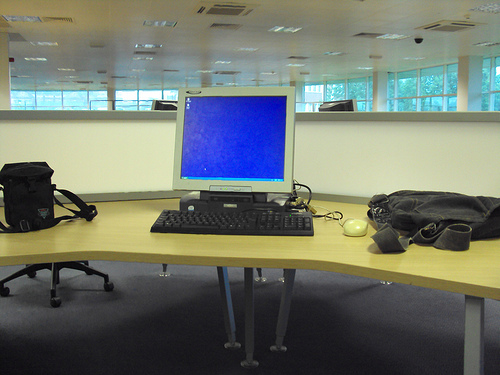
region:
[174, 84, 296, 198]
White monitor on table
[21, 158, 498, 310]
Wooden desk in office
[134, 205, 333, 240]
Black keyboard on wooden desk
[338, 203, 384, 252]
white mouse on wooden desk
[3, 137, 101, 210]
black bag on wooden desk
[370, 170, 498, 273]
black bag on wooden desk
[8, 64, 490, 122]
Office windows in background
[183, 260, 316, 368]
Table legs under desk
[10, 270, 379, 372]
Gray carpet floor in room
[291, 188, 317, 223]
Black electrical wires twisted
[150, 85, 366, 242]
a desktop computer on a desk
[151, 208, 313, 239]
a black computer keyboard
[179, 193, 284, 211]
a CPU of a computer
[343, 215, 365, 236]
a white mouse connected to the computer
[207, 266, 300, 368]
legs of the desk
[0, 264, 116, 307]
legs with wheels of the office chair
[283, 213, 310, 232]
a numeric keypad of the keyboard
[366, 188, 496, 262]
a black bag on the desk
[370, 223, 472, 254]
black straps of the bag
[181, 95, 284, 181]
a blue screen monitor of the computer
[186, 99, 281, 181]
blue screen of computer monitor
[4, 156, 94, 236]
black bag with black strap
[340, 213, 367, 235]
white mouse on desk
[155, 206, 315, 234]
black keyboard on desk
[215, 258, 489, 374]
gray legs of table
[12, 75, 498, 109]
windows lining walls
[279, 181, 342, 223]
black cords on desk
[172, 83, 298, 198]
gray frame of computer monitor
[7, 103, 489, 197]
white dividing wall behind desk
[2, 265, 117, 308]
black wheels on rolling chair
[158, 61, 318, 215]
blue screen on monitor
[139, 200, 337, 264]
black computer keyboard on table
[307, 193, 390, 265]
white mouse on table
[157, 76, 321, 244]
white monitor on black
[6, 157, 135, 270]
black bag on table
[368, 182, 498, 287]
backpack laying on table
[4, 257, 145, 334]
wheels of chair behind table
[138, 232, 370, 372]
legs of table on floor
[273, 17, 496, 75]
air vents in ceiling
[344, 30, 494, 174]
windows and white columns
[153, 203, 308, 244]
a black keyboard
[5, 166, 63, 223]
a black bag on the desk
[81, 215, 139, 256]
a desk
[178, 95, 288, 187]
a computer screen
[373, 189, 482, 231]
clothing on the desk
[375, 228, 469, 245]
a belt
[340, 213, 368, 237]
a mouse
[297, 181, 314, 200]
a black cord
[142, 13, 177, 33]
lights on the ceiling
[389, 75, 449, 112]
clear windows